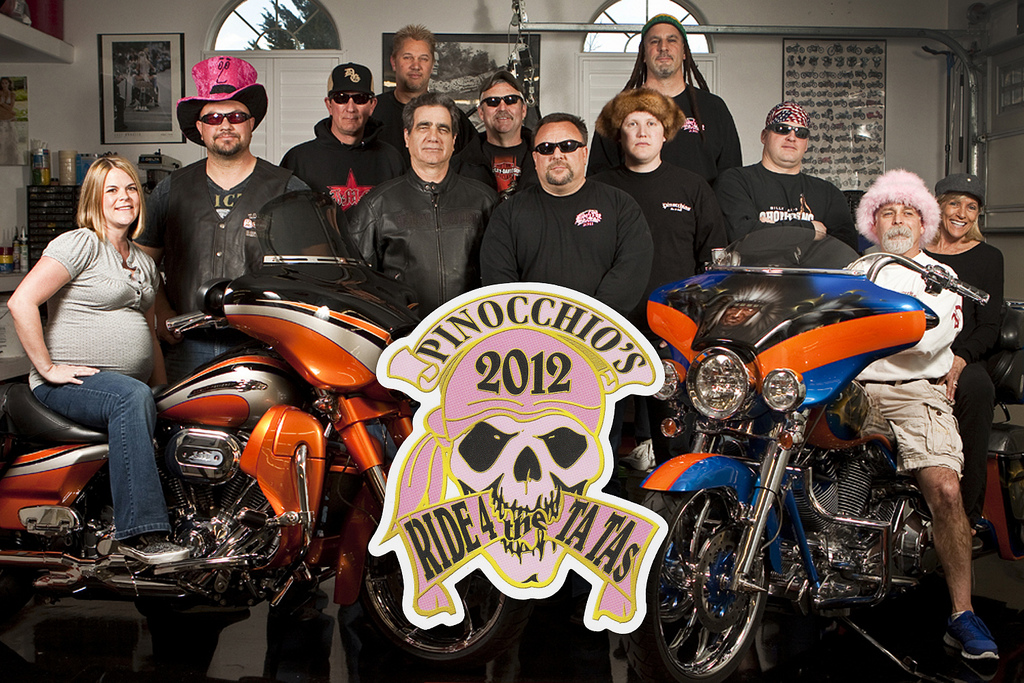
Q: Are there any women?
A: Yes, there is a woman.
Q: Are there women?
A: Yes, there is a woman.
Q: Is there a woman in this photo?
A: Yes, there is a woman.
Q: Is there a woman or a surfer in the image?
A: Yes, there is a woman.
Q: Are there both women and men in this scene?
A: Yes, there are both a woman and a man.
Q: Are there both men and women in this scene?
A: Yes, there are both a woman and a man.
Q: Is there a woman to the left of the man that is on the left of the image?
A: Yes, there is a woman to the left of the man.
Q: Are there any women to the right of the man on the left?
A: No, the woman is to the left of the man.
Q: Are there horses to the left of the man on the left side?
A: No, there is a woman to the left of the man.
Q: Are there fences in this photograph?
A: No, there are no fences.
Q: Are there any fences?
A: No, there are no fences.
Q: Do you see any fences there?
A: No, there are no fences.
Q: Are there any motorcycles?
A: Yes, there is a motorcycle.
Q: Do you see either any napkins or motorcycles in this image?
A: Yes, there is a motorcycle.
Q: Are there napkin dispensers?
A: No, there are no napkin dispensers.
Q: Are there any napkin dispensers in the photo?
A: No, there are no napkin dispensers.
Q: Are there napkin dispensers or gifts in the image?
A: No, there are no napkin dispensers or gifts.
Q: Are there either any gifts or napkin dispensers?
A: No, there are no napkin dispensers or gifts.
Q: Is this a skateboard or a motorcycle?
A: This is a motorcycle.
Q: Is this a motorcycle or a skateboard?
A: This is a motorcycle.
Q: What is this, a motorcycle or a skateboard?
A: This is a motorcycle.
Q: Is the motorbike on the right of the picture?
A: Yes, the motorbike is on the right of the image.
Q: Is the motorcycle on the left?
A: No, the motorcycle is on the right of the image.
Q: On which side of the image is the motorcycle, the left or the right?
A: The motorcycle is on the right of the image.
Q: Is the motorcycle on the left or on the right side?
A: The motorcycle is on the right of the image.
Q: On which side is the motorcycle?
A: The motorcycle is on the right of the image.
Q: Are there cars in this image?
A: No, there are no cars.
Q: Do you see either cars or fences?
A: No, there are no cars or fences.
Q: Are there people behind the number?
A: Yes, there are people behind the number.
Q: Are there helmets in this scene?
A: No, there are no helmets.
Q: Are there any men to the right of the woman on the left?
A: Yes, there is a man to the right of the woman.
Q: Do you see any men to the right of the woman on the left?
A: Yes, there is a man to the right of the woman.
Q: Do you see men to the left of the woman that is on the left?
A: No, the man is to the right of the woman.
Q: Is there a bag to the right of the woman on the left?
A: No, there is a man to the right of the woman.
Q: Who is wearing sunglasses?
A: The man is wearing sunglasses.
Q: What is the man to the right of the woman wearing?
A: The man is wearing sunglasses.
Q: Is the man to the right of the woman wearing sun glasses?
A: Yes, the man is wearing sun glasses.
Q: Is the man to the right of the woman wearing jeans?
A: No, the man is wearing sun glasses.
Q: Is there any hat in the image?
A: Yes, there is a hat.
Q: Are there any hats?
A: Yes, there is a hat.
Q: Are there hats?
A: Yes, there is a hat.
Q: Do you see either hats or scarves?
A: Yes, there is a hat.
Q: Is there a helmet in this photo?
A: No, there are no helmets.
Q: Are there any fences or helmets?
A: No, there are no helmets or fences.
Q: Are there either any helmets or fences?
A: No, there are no helmets or fences.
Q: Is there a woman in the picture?
A: Yes, there is a woman.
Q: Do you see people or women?
A: Yes, there is a woman.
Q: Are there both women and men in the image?
A: Yes, there are both a woman and a man.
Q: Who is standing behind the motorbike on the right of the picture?
A: The woman is standing behind the motorcycle.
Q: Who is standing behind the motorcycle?
A: The woman is standing behind the motorcycle.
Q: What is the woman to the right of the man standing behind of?
A: The woman is standing behind the motorcycle.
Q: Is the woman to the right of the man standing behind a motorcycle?
A: Yes, the woman is standing behind a motorcycle.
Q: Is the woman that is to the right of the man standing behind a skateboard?
A: No, the woman is standing behind a motorcycle.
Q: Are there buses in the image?
A: No, there are no buses.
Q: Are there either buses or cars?
A: No, there are no buses or cars.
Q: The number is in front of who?
A: The number is in front of the people.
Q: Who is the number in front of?
A: The number is in front of the people.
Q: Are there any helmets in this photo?
A: No, there are no helmets.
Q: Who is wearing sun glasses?
A: The man is wearing sun glasses.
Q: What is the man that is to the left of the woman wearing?
A: The man is wearing sun glasses.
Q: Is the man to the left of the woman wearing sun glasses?
A: Yes, the man is wearing sun glasses.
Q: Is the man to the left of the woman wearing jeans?
A: No, the man is wearing sun glasses.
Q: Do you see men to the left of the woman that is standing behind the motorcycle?
A: Yes, there is a man to the left of the woman.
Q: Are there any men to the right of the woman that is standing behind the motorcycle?
A: No, the man is to the left of the woman.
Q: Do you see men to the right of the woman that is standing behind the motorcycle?
A: No, the man is to the left of the woman.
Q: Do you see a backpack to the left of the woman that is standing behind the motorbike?
A: No, there is a man to the left of the woman.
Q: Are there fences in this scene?
A: No, there are no fences.